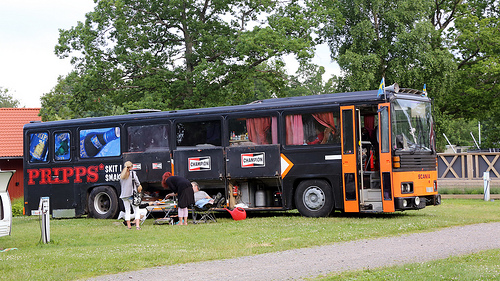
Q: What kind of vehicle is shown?
A: A bus.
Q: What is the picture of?
A: A bus.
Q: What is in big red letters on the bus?
A: Pripps.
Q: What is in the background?
A: Green trees.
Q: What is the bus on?
A: The bus is on grass.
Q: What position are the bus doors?
A: Open.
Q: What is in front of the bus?
A: A gravel path.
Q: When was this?
A: Daytime.